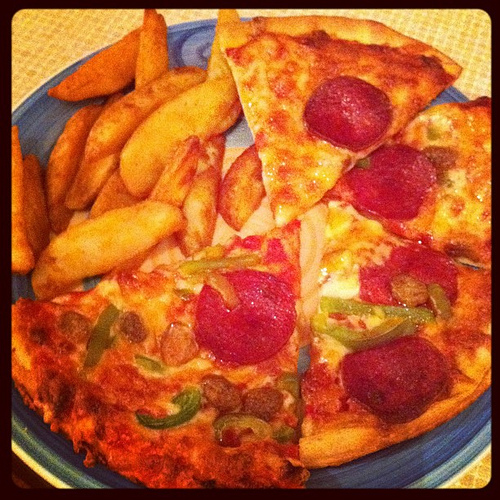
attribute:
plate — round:
[11, 15, 490, 488]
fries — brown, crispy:
[10, 38, 252, 237]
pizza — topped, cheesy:
[206, 21, 479, 439]